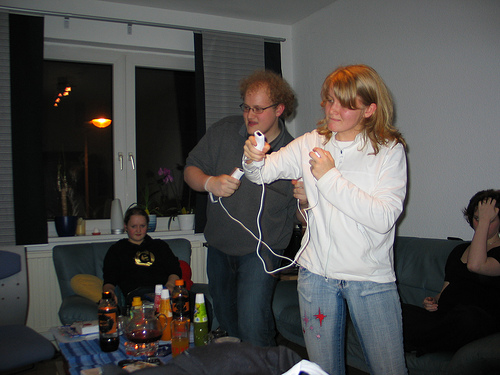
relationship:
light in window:
[86, 115, 113, 128] [39, 58, 118, 243]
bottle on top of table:
[96, 291, 121, 351] [57, 314, 248, 373]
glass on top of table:
[169, 319, 190, 356] [57, 314, 248, 373]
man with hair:
[182, 69, 305, 344] [237, 70, 300, 124]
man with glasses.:
[182, 69, 305, 344] [239, 100, 282, 114]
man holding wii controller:
[182, 69, 305, 344] [217, 165, 311, 236]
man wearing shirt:
[182, 69, 305, 344] [184, 115, 297, 255]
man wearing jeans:
[182, 69, 305, 344] [207, 248, 284, 352]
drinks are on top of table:
[96, 278, 209, 360] [57, 314, 248, 373]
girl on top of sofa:
[402, 189, 499, 355] [273, 235, 500, 374]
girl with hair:
[242, 63, 410, 374] [316, 63, 408, 155]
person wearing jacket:
[242, 63, 410, 374] [243, 125, 408, 282]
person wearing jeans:
[242, 63, 410, 374] [294, 262, 410, 375]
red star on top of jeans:
[314, 306, 326, 327] [294, 262, 410, 375]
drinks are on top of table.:
[96, 278, 209, 360] [57, 314, 248, 373]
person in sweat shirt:
[242, 63, 410, 374] [243, 125, 408, 282]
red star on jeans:
[314, 306, 326, 327] [294, 262, 410, 375]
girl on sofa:
[402, 189, 499, 355] [273, 235, 500, 374]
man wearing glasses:
[182, 69, 305, 344] [239, 100, 282, 114]